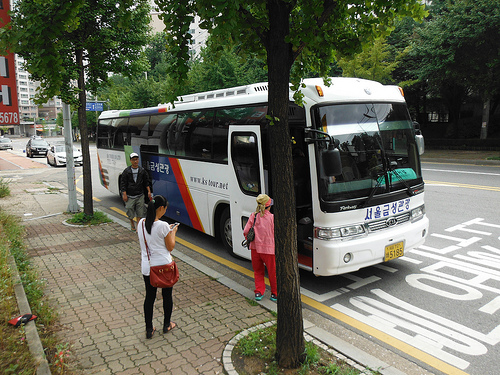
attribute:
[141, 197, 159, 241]
hair — long , black 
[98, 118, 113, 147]
window — glass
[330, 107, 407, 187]
window — glass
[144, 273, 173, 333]
woman's leggings — black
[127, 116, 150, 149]
window — glass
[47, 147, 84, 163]
car — white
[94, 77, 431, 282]
bus — parked 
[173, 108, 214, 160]
window — glass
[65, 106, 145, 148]
sign — blue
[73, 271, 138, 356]
ground — brick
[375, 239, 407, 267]
license plate — yellow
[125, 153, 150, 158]
hat — white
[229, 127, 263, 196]
window — glass